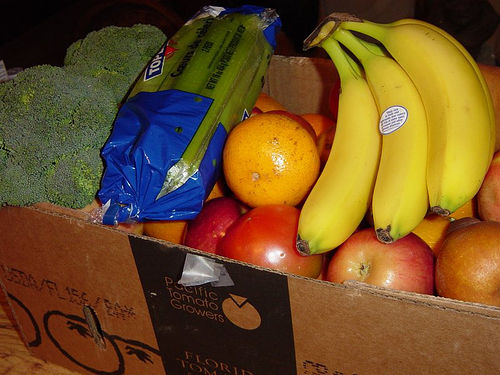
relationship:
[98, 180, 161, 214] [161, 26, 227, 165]
bag with celery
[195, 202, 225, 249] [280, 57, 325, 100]
apple in a box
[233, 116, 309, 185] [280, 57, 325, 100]
orange in a box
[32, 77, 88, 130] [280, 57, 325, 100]
broccoli in a box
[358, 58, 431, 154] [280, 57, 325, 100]
bananas in a box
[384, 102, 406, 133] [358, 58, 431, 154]
stickers on a bananas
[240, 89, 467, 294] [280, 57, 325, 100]
fruit in a box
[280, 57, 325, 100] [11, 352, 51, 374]
box sitting on floor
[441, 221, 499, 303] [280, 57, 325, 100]
pear in a box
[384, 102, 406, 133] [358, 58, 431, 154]
stickers on bananas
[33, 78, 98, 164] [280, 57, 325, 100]
boccoli in a box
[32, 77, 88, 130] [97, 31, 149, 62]
broccoli behind broccoli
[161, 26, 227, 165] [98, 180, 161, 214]
celery in a bag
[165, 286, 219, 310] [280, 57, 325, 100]
tomato written on box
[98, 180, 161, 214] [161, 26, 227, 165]
bag tied in knot for celery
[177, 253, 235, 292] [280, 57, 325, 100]
tape stuck to box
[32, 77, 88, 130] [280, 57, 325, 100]
broccoli in box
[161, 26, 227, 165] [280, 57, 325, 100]
celery that in box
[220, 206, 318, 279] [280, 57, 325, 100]
tomato that are in box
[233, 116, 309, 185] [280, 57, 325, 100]
orange that in box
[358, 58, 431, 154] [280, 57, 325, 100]
bananas that are in box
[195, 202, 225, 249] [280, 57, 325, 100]
apple that in box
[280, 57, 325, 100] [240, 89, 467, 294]
box with fruit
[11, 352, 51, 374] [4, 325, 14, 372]
floor that wooden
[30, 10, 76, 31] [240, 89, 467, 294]
dark background behind fruit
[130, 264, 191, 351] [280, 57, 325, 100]
patch on box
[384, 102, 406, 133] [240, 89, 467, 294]
stickers on fruit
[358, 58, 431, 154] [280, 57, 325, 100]
bananas in box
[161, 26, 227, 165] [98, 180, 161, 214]
celery that in a bag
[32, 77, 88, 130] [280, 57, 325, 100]
broccoli that in box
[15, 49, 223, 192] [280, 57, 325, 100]
vegetables in a box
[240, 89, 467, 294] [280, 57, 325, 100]
fruit that box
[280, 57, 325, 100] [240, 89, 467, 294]
box full of fruit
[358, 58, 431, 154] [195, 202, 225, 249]
bananas sitting on apple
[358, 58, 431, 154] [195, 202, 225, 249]
bananas on top of apple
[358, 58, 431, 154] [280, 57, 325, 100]
bananas on top of apples in box